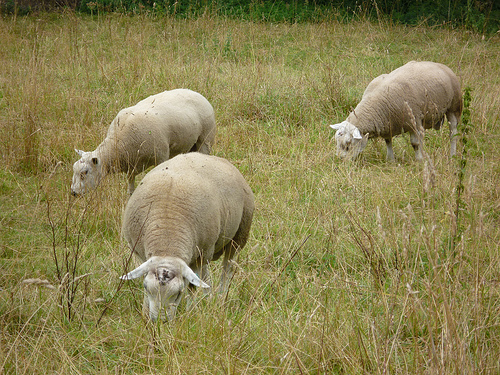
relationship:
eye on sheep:
[341, 139, 350, 151] [118, 151, 255, 325]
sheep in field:
[68, 60, 463, 324] [37, 35, 465, 359]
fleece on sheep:
[142, 172, 206, 244] [118, 151, 255, 325]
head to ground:
[328, 122, 364, 158] [0, 10, 499, 375]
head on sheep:
[328, 122, 364, 158] [331, 59, 466, 168]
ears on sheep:
[322, 119, 370, 147] [322, 51, 466, 185]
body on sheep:
[103, 89, 208, 144] [58, 84, 223, 206]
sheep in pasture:
[103, 133, 262, 310] [32, 12, 472, 348]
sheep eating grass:
[118, 151, 255, 325] [0, 1, 498, 373]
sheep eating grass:
[328, 60, 461, 165] [3, 28, 432, 362]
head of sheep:
[118, 257, 209, 321] [331, 59, 466, 168]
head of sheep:
[118, 257, 209, 321] [118, 151, 255, 325]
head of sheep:
[68, 147, 107, 203] [118, 151, 255, 325]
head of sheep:
[329, 122, 361, 161] [331, 59, 466, 168]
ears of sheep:
[113, 260, 211, 295] [117, 150, 261, 337]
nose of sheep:
[143, 311, 176, 329] [107, 138, 260, 328]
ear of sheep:
[178, 263, 211, 290] [118, 151, 255, 325]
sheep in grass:
[331, 59, 466, 168] [293, 177, 487, 366]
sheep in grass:
[118, 151, 255, 325] [293, 177, 487, 366]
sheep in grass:
[71, 87, 218, 193] [293, 177, 487, 366]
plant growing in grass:
[450, 86, 475, 264] [269, 136, 326, 291]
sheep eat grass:
[118, 151, 255, 325] [0, 1, 498, 373]